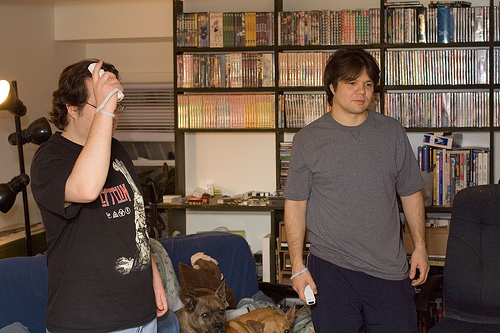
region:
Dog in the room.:
[152, 275, 249, 331]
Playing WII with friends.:
[76, 39, 159, 124]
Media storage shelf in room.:
[191, 5, 312, 128]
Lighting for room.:
[3, 67, 52, 232]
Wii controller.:
[281, 266, 337, 303]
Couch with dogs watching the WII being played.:
[11, 207, 312, 315]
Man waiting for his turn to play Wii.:
[272, 30, 463, 330]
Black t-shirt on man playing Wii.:
[72, 171, 179, 247]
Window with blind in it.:
[93, 65, 235, 235]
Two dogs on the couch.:
[174, 267, 329, 331]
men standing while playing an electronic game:
[21, 30, 429, 297]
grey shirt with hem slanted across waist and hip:
[261, 27, 442, 307]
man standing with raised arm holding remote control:
[40, 41, 147, 216]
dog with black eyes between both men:
[60, 260, 335, 325]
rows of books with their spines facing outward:
[166, 5, 311, 115]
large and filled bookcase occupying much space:
[155, 16, 495, 236]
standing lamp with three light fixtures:
[0, 61, 45, 246]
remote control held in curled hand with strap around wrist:
[265, 232, 335, 304]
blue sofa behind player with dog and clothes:
[10, 210, 305, 325]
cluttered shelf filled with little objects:
[142, 175, 282, 228]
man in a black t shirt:
[48, 61, 168, 331]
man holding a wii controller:
[41, 47, 190, 332]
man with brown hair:
[40, 45, 177, 240]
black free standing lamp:
[8, 82, 51, 262]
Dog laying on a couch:
[164, 277, 239, 330]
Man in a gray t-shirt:
[266, 37, 458, 324]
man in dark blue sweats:
[276, 40, 405, 332]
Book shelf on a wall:
[167, 12, 467, 162]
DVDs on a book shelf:
[176, 14, 388, 128]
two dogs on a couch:
[168, 235, 313, 332]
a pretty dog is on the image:
[188, 295, 235, 328]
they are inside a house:
[90, 22, 461, 329]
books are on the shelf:
[178, 28, 315, 150]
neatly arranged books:
[392, 17, 499, 98]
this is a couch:
[169, 241, 265, 319]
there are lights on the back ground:
[1, 76, 28, 208]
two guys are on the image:
[47, 67, 383, 312]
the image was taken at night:
[127, 63, 252, 296]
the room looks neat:
[9, 38, 463, 277]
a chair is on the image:
[448, 211, 496, 287]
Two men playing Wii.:
[27, 41, 435, 332]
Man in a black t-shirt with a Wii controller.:
[27, 50, 171, 331]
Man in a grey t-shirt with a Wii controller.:
[280, 46, 432, 331]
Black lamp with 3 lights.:
[1, 71, 55, 253]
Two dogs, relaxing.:
[171, 283, 293, 331]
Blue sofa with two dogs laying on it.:
[0, 228, 300, 332]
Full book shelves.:
[172, 1, 498, 127]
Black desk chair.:
[415, 181, 499, 331]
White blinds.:
[112, 84, 177, 143]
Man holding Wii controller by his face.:
[27, 56, 169, 331]